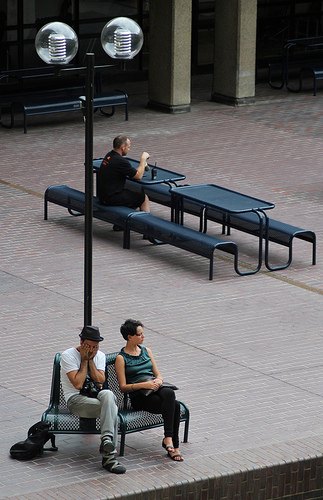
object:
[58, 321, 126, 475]
man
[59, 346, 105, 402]
shirt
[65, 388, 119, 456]
jeans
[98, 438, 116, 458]
shoe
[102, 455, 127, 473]
shoe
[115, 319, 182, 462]
woman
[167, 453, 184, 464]
sandal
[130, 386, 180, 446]
pants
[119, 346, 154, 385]
shirt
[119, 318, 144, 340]
hair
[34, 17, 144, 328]
lamp post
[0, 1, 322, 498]
plaza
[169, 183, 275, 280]
table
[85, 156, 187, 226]
table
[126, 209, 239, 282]
bench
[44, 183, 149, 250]
bench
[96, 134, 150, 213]
man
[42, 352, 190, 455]
bench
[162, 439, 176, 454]
foot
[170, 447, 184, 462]
foot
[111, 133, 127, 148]
hair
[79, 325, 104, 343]
hat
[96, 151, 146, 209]
clothing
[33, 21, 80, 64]
globe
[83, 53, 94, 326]
post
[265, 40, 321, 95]
bicycle rack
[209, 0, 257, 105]
support column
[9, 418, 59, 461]
backpack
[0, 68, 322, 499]
ground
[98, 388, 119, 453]
leg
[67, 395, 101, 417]
leg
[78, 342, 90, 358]
hand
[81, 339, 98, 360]
face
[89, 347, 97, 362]
hand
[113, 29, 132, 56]
spiral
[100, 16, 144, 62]
globe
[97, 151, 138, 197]
shirt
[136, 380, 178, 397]
bag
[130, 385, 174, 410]
lap